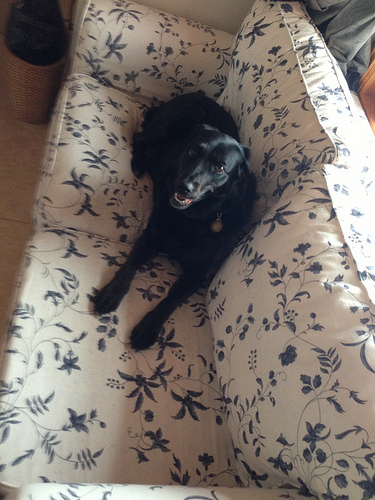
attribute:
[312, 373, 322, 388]
leaf — black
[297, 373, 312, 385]
leaf — black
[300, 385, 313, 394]
leaf — black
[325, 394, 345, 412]
leaf — black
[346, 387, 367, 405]
leaf — black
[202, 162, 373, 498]
material — white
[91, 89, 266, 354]
dog — black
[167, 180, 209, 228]
mouth — open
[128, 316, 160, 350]
paw — black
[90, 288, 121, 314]
paw — black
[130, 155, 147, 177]
paw — black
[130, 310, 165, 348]
paws — black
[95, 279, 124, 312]
paws — black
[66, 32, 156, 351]
sofa — white, blue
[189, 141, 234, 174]
eyes — brown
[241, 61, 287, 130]
print — flowered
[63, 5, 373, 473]
couch — designed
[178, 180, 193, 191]
nose — black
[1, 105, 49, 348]
floor — brown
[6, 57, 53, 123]
basket — wicker, tan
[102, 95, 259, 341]
fur — black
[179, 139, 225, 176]
eyes — brown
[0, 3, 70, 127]
basket — wicker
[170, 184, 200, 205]
mouth — open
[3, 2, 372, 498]
couch — white, blue